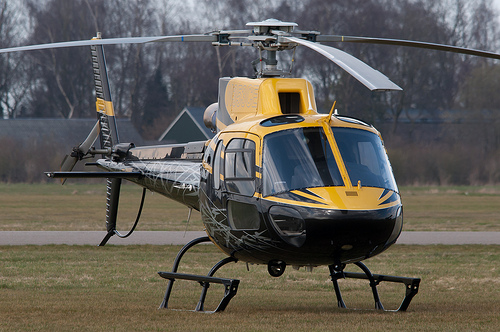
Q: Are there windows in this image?
A: Yes, there is a window.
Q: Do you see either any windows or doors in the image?
A: Yes, there is a window.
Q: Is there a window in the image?
A: Yes, there is a window.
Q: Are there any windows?
A: Yes, there is a window.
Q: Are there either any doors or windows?
A: Yes, there is a window.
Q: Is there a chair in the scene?
A: No, there are no chairs.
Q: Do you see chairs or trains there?
A: No, there are no chairs or trains.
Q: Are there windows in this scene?
A: Yes, there is a window.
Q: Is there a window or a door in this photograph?
A: Yes, there is a window.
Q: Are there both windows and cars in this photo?
A: No, there is a window but no cars.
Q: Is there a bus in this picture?
A: No, there are no buses.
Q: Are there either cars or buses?
A: No, there are no buses or cars.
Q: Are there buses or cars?
A: No, there are no buses or cars.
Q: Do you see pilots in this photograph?
A: No, there are no pilots.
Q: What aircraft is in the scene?
A: The aircraft is a helicopter.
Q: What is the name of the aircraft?
A: The aircraft is a helicopter.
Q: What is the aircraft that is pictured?
A: The aircraft is a helicopter.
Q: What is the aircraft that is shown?
A: The aircraft is a helicopter.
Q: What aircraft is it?
A: The aircraft is a helicopter.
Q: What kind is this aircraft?
A: That is a helicopter.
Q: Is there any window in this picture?
A: Yes, there is a window.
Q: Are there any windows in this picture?
A: Yes, there is a window.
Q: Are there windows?
A: Yes, there is a window.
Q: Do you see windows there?
A: Yes, there is a window.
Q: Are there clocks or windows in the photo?
A: Yes, there is a window.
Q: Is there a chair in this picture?
A: No, there are no chairs.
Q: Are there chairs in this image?
A: No, there are no chairs.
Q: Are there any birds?
A: No, there are no birds.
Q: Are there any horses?
A: No, there are no horses.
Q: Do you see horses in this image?
A: No, there are no horses.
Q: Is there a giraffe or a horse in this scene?
A: No, there are no horses or giraffes.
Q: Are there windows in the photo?
A: Yes, there is a window.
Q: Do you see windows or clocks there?
A: Yes, there is a window.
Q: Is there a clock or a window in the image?
A: Yes, there is a window.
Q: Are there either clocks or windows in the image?
A: Yes, there is a window.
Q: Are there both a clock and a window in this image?
A: No, there is a window but no clocks.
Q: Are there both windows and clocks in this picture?
A: No, there is a window but no clocks.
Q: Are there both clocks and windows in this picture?
A: No, there is a window but no clocks.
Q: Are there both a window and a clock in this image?
A: No, there is a window but no clocks.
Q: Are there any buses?
A: No, there are no buses.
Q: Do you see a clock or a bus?
A: No, there are no buses or clocks.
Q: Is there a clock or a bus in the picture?
A: No, there are no buses or clocks.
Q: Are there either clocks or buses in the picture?
A: No, there are no buses or clocks.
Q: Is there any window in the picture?
A: Yes, there is a window.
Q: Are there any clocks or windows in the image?
A: Yes, there is a window.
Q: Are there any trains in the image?
A: No, there are no trains.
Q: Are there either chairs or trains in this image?
A: No, there are no trains or chairs.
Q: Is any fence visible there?
A: No, there are no fences.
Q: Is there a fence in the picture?
A: No, there are no fences.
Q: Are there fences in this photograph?
A: No, there are no fences.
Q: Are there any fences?
A: No, there are no fences.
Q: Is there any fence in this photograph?
A: No, there are no fences.